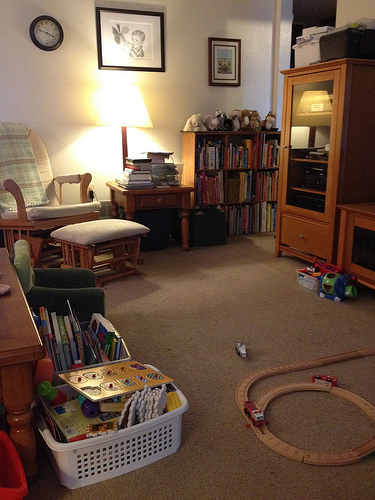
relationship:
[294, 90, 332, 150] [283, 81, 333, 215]
lamp reflection in glass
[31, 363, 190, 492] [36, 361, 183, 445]
laundry basket full of kids' stuff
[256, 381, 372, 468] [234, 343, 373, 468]
loop on track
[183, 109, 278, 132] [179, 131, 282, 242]
stuffed animals sitting on shelf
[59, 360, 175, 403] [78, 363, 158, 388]
puzzle has knobs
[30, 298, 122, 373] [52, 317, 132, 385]
books in bin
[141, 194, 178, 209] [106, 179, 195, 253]
drawer on end table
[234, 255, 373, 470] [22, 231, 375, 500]
toys on floor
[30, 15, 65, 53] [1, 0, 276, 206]
clock on wall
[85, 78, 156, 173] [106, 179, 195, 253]
lamp on end table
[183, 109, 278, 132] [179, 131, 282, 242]
stuffed animals on top of shelf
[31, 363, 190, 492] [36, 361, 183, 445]
laundry basket filled with kids' stuff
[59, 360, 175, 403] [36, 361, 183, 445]
puzzle on top of kids' stuff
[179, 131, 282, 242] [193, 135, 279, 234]
shelf full of books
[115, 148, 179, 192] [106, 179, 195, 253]
books on top of end table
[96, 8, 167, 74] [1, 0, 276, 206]
framed art on wall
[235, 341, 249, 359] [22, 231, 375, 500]
toy on floor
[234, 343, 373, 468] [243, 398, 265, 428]
track has train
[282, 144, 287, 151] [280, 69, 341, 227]
handle on door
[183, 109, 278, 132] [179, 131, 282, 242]
stuffed animals on shelf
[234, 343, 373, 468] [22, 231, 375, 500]
track on floor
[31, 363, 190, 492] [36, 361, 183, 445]
laundry basket holding kids' stuff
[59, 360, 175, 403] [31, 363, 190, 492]
puzzle on top of laundry basket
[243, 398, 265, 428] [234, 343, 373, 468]
train on track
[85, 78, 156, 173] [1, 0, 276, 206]
lamp against wall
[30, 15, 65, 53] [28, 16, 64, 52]
clock has frame